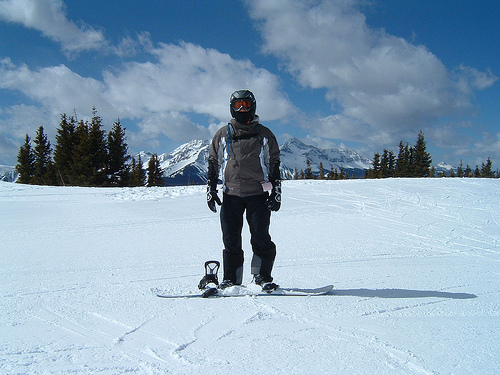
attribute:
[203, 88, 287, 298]
snowboarder — looking, young, ready to snowboard, standing, tall, dressed to snowboard, having picture taken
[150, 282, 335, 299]
snowboard — covered in snow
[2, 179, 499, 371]
snow — on ground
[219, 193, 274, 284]
ski pants — dark, black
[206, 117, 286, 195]
ski jacket — dark, black, grey, white, gray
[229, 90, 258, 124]
helmet — black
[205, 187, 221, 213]
glove — black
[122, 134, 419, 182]
mountain — snowy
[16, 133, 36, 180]
tree — in background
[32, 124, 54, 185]
tree — in background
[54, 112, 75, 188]
tree — in background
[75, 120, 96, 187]
tree — in background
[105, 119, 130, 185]
tree — in background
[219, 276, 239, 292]
snowboot — black, gray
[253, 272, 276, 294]
snowboot — grey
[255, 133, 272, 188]
side stripe — white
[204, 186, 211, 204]
design — white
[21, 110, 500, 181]
forest — mountainous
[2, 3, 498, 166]
sky — blue